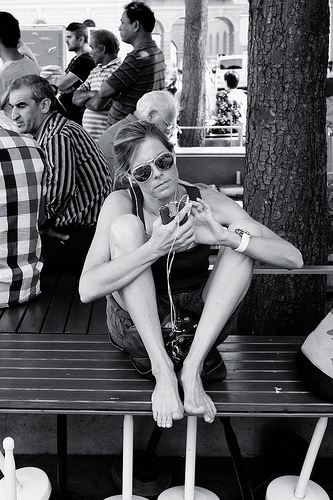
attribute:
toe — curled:
[188, 401, 207, 419]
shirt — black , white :
[29, 105, 114, 229]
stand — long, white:
[212, 54, 252, 141]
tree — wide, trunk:
[230, 0, 332, 354]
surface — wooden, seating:
[22, 322, 305, 413]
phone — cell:
[158, 200, 195, 241]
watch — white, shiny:
[233, 225, 251, 257]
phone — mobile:
[153, 198, 188, 224]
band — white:
[232, 233, 251, 252]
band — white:
[236, 233, 250, 250]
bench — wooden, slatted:
[0, 247, 330, 498]